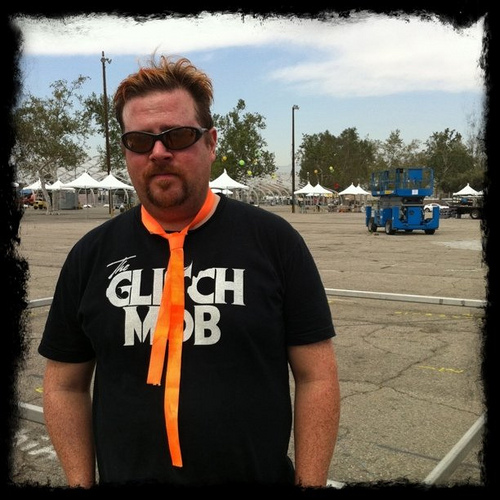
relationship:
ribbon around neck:
[138, 189, 223, 470] [148, 192, 213, 237]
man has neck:
[37, 44, 342, 484] [148, 192, 213, 237]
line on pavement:
[329, 287, 484, 312] [20, 202, 482, 483]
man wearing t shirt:
[37, 44, 342, 484] [41, 191, 309, 491]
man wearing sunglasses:
[67, 77, 324, 484] [120, 125, 214, 157]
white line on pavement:
[418, 407, 485, 481] [20, 202, 482, 483]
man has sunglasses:
[37, 44, 342, 484] [109, 117, 226, 151]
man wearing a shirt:
[37, 44, 342, 484] [86, 197, 338, 448]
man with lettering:
[37, 44, 342, 484] [33, 237, 266, 372]